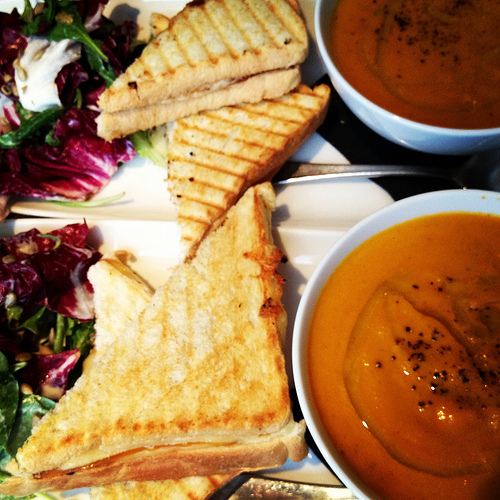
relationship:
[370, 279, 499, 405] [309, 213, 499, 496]
condiment in soup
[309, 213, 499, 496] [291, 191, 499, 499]
soup in bowl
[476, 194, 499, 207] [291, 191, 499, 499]
soup stains on bowl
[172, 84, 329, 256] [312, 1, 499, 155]
bread next to bowl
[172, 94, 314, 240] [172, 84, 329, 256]
lines on bread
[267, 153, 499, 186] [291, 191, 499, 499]
spoon next to bowl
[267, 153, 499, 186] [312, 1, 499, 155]
spoon on bowl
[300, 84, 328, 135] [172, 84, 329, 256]
crust of bread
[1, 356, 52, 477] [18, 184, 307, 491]
leaves next to sandwich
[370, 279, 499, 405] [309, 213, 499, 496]
condiment on top of soup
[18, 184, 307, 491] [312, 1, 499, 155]
sandwich on bowl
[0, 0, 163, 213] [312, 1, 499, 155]
salad on side of bowl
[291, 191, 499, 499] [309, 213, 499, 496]
bowl of soup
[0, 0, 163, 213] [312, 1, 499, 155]
salad on bowl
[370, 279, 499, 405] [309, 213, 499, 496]
condiment on soup